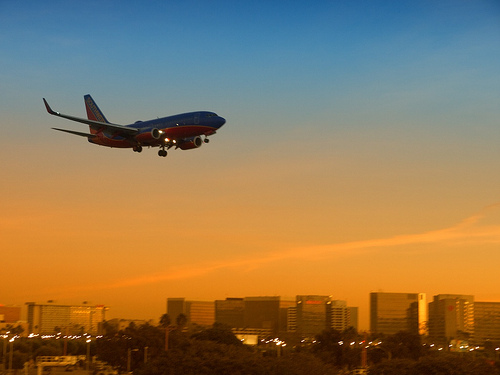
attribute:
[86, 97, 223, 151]
plane — tail 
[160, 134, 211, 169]
wheel — right back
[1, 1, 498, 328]
sky — blue , some, two-tone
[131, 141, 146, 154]
back wheel — left back 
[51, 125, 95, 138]
side wing —  left side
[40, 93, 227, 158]
plane — tail , body , under 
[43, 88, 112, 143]
tail fin — tail 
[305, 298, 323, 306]
sign — red, glowing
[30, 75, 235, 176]
plane — low-flying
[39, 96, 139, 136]
wing —  left side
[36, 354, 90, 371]
structure — white